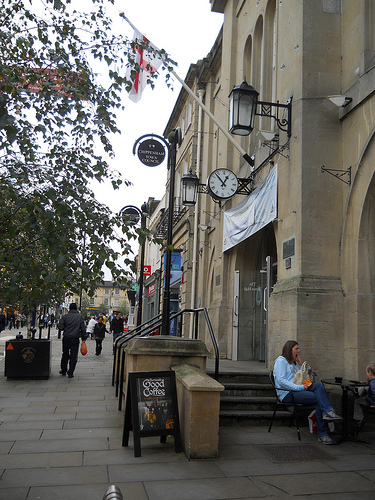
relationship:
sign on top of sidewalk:
[122, 372, 188, 458] [8, 457, 374, 499]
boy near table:
[351, 362, 374, 443] [322, 373, 366, 448]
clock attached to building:
[209, 170, 239, 201] [123, 1, 371, 452]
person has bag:
[59, 303, 88, 379] [77, 336, 89, 357]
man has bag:
[59, 303, 88, 379] [77, 336, 89, 357]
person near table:
[271, 339, 345, 446] [322, 373, 366, 448]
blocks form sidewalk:
[42, 427, 121, 443] [8, 457, 374, 499]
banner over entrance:
[219, 164, 280, 252] [227, 223, 282, 373]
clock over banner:
[209, 170, 239, 201] [219, 164, 280, 252]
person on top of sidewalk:
[91, 315, 107, 356] [1, 372, 115, 496]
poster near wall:
[219, 164, 280, 252] [226, 0, 309, 340]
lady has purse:
[271, 339, 345, 446] [297, 361, 314, 386]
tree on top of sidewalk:
[2, 187, 79, 339] [1, 372, 115, 496]